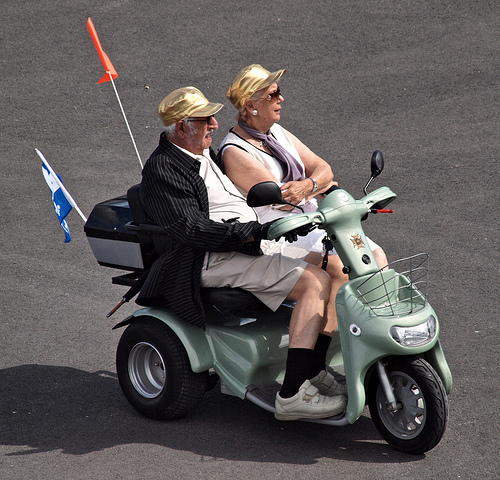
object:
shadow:
[0, 362, 427, 465]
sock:
[284, 331, 333, 385]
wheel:
[365, 354, 450, 457]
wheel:
[115, 315, 210, 420]